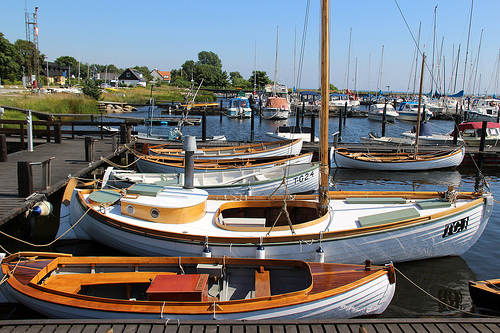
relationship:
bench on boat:
[253, 269, 270, 304] [11, 242, 394, 314]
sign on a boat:
[441, 216, 467, 237] [62, 0, 494, 260]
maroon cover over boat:
[449, 121, 500, 138] [445, 120, 499, 147]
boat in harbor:
[3, 227, 420, 329] [184, 67, 472, 294]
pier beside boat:
[0, 316, 497, 331] [0, 251, 395, 321]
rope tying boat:
[397, 259, 462, 325] [8, 230, 408, 307]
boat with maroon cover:
[459, 122, 497, 127] [442, 115, 498, 157]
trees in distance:
[168, 50, 280, 88] [11, 46, 476, 98]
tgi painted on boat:
[443, 217, 468, 237] [63, 172, 485, 263]